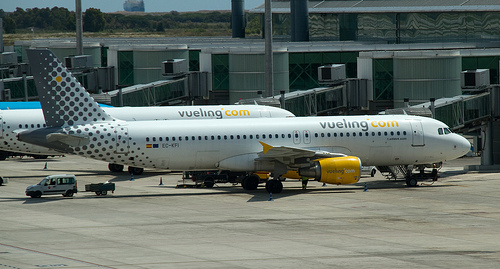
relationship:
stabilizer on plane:
[25, 45, 116, 127] [15, 47, 471, 194]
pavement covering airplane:
[1, 153, 484, 266] [14, 42, 470, 195]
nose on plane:
[445, 125, 477, 175] [70, 104, 444, 169]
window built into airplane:
[144, 135, 152, 143] [14, 42, 470, 195]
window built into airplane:
[262, 134, 266, 138] [14, 42, 470, 195]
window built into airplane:
[223, 134, 228, 138] [14, 42, 470, 195]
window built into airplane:
[224, 135, 227, 139] [14, 42, 470, 195]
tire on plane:
[406, 176, 417, 187] [15, 47, 471, 194]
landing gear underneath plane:
[241, 172, 283, 196] [15, 47, 471, 194]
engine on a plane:
[305, 155, 366, 187] [19, 65, 486, 203]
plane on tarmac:
[15, 47, 471, 194] [0, 159, 499, 266]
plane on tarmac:
[0, 100, 299, 150] [0, 159, 499, 266]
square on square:
[41, 228, 128, 258] [391, 188, 488, 216]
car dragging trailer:
[24, 174, 78, 197] [85, 182, 114, 197]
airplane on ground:
[14, 42, 485, 201] [125, 194, 465, 264]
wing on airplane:
[218, 132, 352, 199] [14, 42, 470, 195]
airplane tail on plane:
[18, 48, 118, 123] [8, 70, 475, 212]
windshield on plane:
[436, 125, 456, 135] [15, 47, 471, 194]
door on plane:
[408, 120, 426, 152] [23, 71, 489, 168]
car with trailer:
[24, 174, 78, 197] [85, 182, 114, 197]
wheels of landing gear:
[240, 176, 260, 190] [265, 175, 284, 193]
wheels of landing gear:
[241, 172, 261, 191] [265, 175, 284, 193]